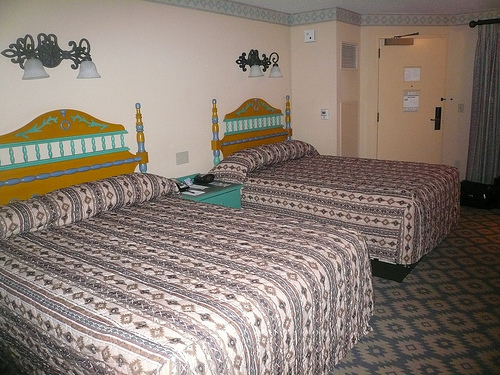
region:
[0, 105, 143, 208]
green and brown headboards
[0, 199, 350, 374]
brown and tan bedclothes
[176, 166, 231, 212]
green table between beds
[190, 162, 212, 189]
black phone on table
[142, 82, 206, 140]
white wall behind beds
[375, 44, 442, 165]
peach colored door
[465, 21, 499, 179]
grey curtain across from beds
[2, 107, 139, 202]
brown and green headboards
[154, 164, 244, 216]
green table between beds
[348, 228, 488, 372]
carpet is brown and grey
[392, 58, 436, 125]
white notices on door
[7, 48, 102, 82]
lights hanging over bed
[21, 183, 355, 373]
brown and grey satin blanket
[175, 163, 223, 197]
black telephone on table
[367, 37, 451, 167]
peach door in room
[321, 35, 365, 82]
grey vent near door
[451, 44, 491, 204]
green curtain near door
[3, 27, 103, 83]
reading lamps mounted to the wall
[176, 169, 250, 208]
green night table between the beds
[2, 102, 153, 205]
colorful headboard on the bed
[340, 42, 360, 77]
vent in the wall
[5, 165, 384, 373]
comforter on the bed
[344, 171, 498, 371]
blue and white pattern on the carpet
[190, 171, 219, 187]
alarm clock on the night stand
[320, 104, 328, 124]
thermostat on the wall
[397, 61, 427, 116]
notices on the back of the door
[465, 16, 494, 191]
curtains covering the window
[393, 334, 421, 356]
pattern on the floor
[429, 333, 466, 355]
pattern on the floor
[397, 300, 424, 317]
pattern on the floor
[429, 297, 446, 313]
pattern on the floor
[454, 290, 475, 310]
pattern on the floor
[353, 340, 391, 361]
pattern on the floor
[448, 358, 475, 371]
pattern on the floor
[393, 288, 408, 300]
pattern on the floor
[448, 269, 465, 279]
pattern on the floor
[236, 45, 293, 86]
lights on the wall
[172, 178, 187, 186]
a phone on the desk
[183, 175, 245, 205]
a green desk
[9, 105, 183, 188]
the headboard on the bed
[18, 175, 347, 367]
a white and black bed spread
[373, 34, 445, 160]
the door to the room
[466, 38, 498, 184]
curtains hanging in front of the window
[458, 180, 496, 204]
a suitcase on the floor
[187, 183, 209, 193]
papers on the table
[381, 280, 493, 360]
the blue and tan carpet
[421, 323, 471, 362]
multi colored floor carpet with diamond design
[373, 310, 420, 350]
multi colored floor carpet with diamond design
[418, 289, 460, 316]
multi colored floor carpet with diamond design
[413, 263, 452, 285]
multi colored floor carpet with diamond design